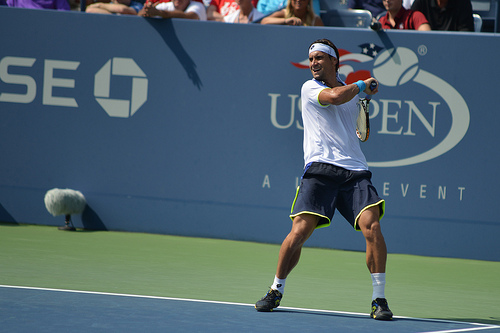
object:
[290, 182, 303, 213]
stripe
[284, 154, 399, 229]
shorts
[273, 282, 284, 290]
symbol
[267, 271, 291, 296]
sock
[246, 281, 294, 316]
sneaker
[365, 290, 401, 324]
sneaker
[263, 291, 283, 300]
laces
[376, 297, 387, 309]
laces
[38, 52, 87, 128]
word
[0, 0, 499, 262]
background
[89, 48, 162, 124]
octagon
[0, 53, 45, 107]
letters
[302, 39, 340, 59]
headband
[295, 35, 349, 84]
head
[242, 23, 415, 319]
man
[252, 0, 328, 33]
spectators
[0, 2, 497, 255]
stand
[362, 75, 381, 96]
hand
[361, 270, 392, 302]
sock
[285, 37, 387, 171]
top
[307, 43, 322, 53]
emblem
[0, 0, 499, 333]
tennis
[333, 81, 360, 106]
quadriceps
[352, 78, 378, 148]
racket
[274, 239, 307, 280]
calf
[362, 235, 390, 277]
calf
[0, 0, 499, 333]
competition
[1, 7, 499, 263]
advertising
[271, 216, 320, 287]
leg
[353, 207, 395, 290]
leg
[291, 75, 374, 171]
t-shirt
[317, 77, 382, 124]
arms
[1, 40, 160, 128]
logo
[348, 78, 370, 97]
armband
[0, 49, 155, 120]
sponsor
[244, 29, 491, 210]
name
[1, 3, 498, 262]
wall